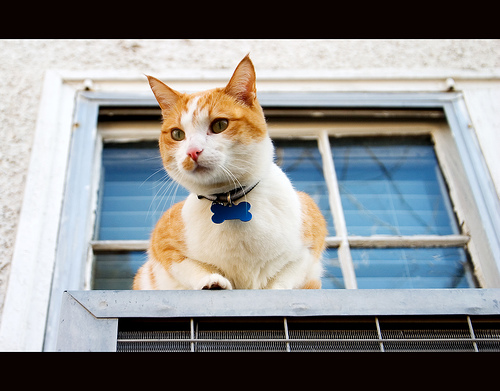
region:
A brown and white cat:
[130, 55, 367, 342]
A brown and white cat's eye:
[197, 100, 237, 145]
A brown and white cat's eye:
[145, 103, 185, 142]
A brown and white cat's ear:
[226, 55, 264, 88]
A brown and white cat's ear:
[137, 68, 182, 106]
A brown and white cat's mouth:
[190, 162, 222, 187]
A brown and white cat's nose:
[169, 145, 209, 162]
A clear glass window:
[330, 124, 449, 290]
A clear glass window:
[81, 103, 146, 228]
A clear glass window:
[269, 130, 329, 182]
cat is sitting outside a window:
[0, 40, 495, 346]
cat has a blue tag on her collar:
[125, 50, 320, 290]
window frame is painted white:
[0, 65, 495, 350]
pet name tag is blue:
[210, 190, 250, 220]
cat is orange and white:
[130, 50, 325, 287]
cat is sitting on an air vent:
[0, 36, 495, 346]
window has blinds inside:
[0, 67, 496, 348]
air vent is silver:
[57, 286, 493, 351]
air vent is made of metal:
[54, 285, 497, 352]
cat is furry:
[129, 49, 326, 287]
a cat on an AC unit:
[107, 61, 359, 303]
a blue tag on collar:
[195, 197, 272, 238]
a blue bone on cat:
[204, 202, 261, 227]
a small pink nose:
[184, 144, 204, 163]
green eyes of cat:
[151, 109, 238, 149]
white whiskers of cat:
[133, 155, 278, 216]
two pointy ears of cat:
[122, 57, 278, 119]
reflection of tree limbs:
[284, 137, 475, 291]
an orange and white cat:
[66, 62, 345, 294]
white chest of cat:
[175, 202, 301, 292]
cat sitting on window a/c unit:
[146, 88, 296, 239]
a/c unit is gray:
[335, 298, 370, 322]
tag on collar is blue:
[208, 196, 288, 236]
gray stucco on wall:
[12, 78, 42, 111]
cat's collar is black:
[235, 189, 262, 191]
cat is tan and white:
[153, 95, 261, 227]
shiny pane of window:
[397, 156, 407, 209]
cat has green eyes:
[206, 116, 253, 145]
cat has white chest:
[205, 217, 270, 279]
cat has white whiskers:
[156, 160, 187, 215]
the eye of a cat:
[211, 118, 228, 135]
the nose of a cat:
[184, 147, 203, 160]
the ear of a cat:
[136, 61, 185, 111]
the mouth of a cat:
[188, 165, 211, 176]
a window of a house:
[303, 93, 481, 305]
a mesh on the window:
[199, 330, 284, 337]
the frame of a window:
[35, 76, 91, 298]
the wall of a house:
[6, 48, 41, 130]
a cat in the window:
[114, 51, 314, 282]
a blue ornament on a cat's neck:
[201, 198, 255, 225]